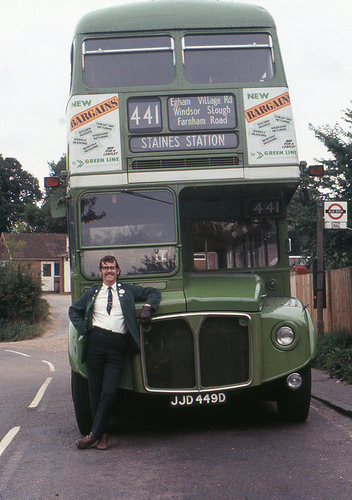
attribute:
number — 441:
[124, 98, 167, 132]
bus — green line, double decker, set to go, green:
[60, 4, 325, 438]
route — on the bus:
[138, 130, 230, 156]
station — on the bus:
[169, 92, 242, 129]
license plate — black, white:
[166, 388, 233, 409]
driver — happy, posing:
[64, 254, 163, 459]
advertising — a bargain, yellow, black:
[65, 89, 120, 183]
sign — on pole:
[315, 192, 348, 321]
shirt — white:
[92, 282, 132, 340]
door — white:
[39, 260, 58, 294]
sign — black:
[123, 94, 246, 159]